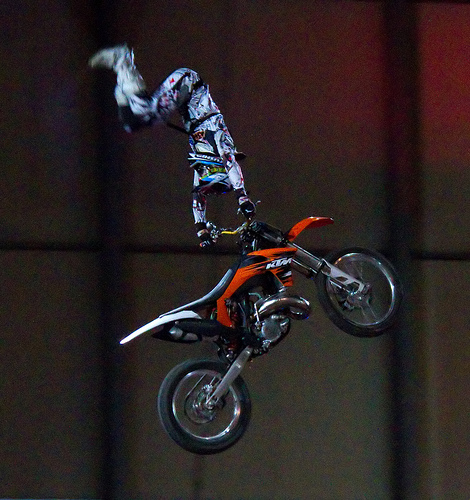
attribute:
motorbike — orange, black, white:
[118, 219, 404, 454]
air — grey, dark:
[3, 7, 467, 493]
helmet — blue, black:
[191, 159, 238, 200]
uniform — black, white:
[143, 67, 242, 193]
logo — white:
[255, 256, 298, 271]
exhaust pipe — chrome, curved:
[241, 296, 310, 324]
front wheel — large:
[318, 245, 408, 338]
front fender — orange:
[291, 208, 334, 242]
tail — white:
[117, 305, 199, 349]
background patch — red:
[237, 1, 469, 174]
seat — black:
[155, 266, 242, 316]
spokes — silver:
[331, 254, 398, 325]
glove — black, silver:
[189, 224, 215, 249]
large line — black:
[2, 241, 468, 262]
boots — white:
[87, 42, 143, 110]